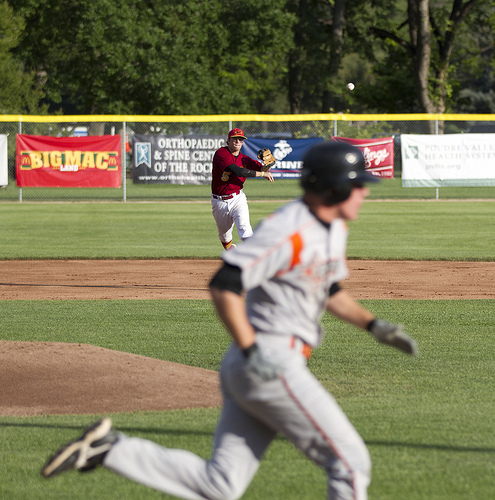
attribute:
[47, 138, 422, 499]
player — person, playing baseball, runnin, running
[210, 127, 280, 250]
player — pitching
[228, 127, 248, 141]
cap — red colored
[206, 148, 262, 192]
shirt — dark red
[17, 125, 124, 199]
ad — poster, large, for big mac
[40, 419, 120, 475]
sneaker — black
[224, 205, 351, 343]
jersey — orange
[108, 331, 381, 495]
pants — white, grey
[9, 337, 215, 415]
pitcher's mound — dirty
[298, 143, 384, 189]
helmet — black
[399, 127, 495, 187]
banner — white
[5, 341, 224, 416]
mound — pitcher's mound